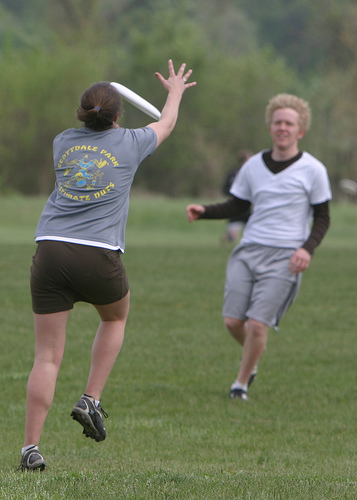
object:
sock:
[94, 400, 99, 406]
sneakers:
[17, 399, 127, 470]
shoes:
[19, 441, 48, 469]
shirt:
[44, 128, 139, 245]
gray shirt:
[34, 126, 159, 252]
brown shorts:
[28, 237, 128, 315]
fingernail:
[155, 72, 159, 77]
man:
[182, 88, 334, 404]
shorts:
[221, 238, 305, 334]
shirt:
[201, 130, 334, 255]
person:
[19, 58, 201, 469]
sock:
[21, 444, 37, 457]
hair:
[264, 91, 309, 132]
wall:
[152, 78, 233, 174]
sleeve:
[301, 199, 330, 256]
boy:
[185, 95, 330, 396]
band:
[94, 105, 102, 111]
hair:
[78, 81, 123, 127]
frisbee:
[109, 78, 161, 122]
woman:
[17, 57, 197, 475]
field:
[0, 206, 357, 494]